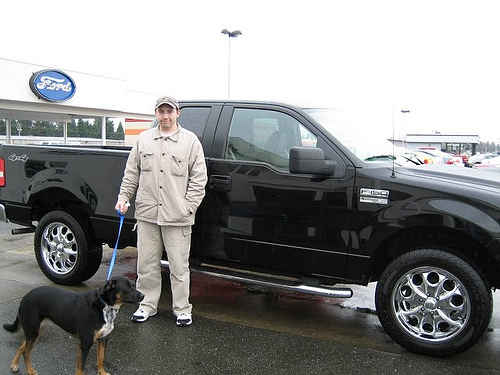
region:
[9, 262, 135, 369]
dog on a leash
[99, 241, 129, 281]
blue leash for the dog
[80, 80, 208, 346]
man with the dog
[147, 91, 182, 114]
hat on the man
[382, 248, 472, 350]
tire on the truck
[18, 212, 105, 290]
tire on the truck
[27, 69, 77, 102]
logo on the building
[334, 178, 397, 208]
make of the truck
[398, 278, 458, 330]
wheel of the truck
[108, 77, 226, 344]
this is a truck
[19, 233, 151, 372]
this is a dog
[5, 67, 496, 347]
this is a truck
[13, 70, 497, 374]
the truck is black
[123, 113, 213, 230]
man is wearing a jacket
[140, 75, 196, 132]
man is wearing a hat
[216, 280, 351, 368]
the ground is wet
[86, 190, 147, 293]
blue leash on dog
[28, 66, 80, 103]
a blue and white oval "Ford" sign on a building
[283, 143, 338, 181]
the rear view mirror of a truck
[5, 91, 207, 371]
a man and a dog standing in front of a truck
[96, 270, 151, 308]
the head of a dog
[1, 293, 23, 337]
the tail of a dog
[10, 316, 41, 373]
the hind legs of a dog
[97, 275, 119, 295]
an ear of a dog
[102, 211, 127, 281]
a blue leash for a dog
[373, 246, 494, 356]
a wheel of a truck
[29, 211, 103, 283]
a wheel of a truck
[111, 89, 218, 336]
man with a tan jacket standing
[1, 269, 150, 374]
dog next to a person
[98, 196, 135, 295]
blue leash in a persons hand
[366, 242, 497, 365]
front wheel on a vehicle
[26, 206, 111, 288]
rear wheel on a vehicle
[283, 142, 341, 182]
side rear view mirror on a vehicle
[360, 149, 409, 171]
windshield wiper on a vehicle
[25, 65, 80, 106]
sign on a building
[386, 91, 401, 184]
antenna on a vehicle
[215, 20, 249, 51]
lights on a pole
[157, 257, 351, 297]
side step on the truck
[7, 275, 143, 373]
a black and brown dog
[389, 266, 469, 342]
silver tire rims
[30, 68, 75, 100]
brand name on the building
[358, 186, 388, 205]
silver emblems on the truck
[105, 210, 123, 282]
a blue dog leash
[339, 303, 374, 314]
a puddle on the ground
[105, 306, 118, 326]
black spots on the dog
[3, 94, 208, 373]
Man with a dog on a leash.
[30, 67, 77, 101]
Ford sign on the building.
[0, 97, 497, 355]
Shiny black truck in the parking lot.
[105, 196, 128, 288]
Blue dog leash in the man's hand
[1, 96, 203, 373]
a man and a dog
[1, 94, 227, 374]
a man holding a blue leash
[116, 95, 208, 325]
a man wearing a beige hat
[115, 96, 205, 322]
a man wearing a beige jacket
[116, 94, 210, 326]
a man wearing beige pants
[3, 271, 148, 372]
a black and brown dog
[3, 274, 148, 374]
a dog with a white patch on his chest area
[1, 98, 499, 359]
a black 4X4 pick up truck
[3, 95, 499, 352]
a truck with silver rims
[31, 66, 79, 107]
a ford dealership sign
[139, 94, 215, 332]
man in khaki pants and jacket